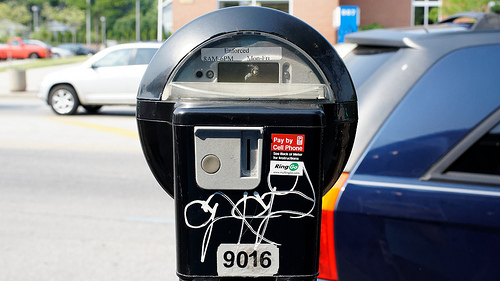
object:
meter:
[134, 5, 359, 280]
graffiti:
[180, 160, 318, 262]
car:
[318, 26, 500, 279]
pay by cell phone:
[269, 134, 305, 152]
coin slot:
[245, 141, 253, 172]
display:
[214, 60, 279, 85]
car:
[26, 40, 165, 117]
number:
[220, 250, 236, 268]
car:
[0, 34, 50, 61]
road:
[0, 102, 179, 280]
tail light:
[318, 171, 353, 280]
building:
[158, 3, 497, 44]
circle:
[134, 5, 359, 198]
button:
[200, 154, 222, 174]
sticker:
[268, 160, 305, 176]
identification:
[216, 243, 279, 278]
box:
[171, 107, 328, 280]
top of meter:
[137, 4, 360, 198]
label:
[200, 44, 283, 63]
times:
[202, 55, 234, 62]